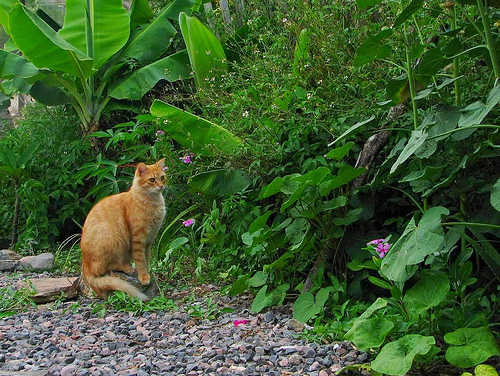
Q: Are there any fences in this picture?
A: No, there are no fences.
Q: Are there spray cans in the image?
A: No, there are no spray cans.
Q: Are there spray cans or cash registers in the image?
A: No, there are no spray cans or cash registers.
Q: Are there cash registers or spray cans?
A: No, there are no spray cans or cash registers.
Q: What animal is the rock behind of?
A: The rock is behind the cat.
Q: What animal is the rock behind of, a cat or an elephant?
A: The rock is behind a cat.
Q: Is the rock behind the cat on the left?
A: Yes, the rock is behind the cat.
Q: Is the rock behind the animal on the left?
A: Yes, the rock is behind the cat.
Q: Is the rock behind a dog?
A: No, the rock is behind the cat.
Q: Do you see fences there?
A: No, there are no fences.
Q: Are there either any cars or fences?
A: No, there are no fences or cars.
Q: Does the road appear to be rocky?
A: Yes, the road is rocky.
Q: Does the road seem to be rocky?
A: Yes, the road is rocky.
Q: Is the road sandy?
A: No, the road is rocky.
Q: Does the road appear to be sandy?
A: No, the road is rocky.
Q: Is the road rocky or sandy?
A: The road is rocky.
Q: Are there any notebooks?
A: No, there are no notebooks.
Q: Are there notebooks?
A: No, there are no notebooks.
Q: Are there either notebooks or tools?
A: No, there are no notebooks or tools.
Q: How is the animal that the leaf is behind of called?
A: The animal is a cat.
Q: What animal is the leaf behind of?
A: The leaf is behind the cat.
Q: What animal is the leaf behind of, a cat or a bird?
A: The leaf is behind a cat.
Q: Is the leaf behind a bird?
A: No, the leaf is behind the cat.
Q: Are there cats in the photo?
A: Yes, there is a cat.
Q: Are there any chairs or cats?
A: Yes, there is a cat.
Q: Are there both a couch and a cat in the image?
A: No, there is a cat but no couches.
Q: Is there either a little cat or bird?
A: Yes, there is a little cat.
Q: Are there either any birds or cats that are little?
A: Yes, the cat is little.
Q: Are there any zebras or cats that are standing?
A: Yes, the cat is standing.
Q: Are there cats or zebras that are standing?
A: Yes, the cat is standing.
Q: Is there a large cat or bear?
A: Yes, there is a large cat.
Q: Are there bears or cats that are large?
A: Yes, the cat is large.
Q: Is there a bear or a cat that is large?
A: Yes, the cat is large.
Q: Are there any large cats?
A: Yes, there is a large cat.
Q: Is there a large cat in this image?
A: Yes, there is a large cat.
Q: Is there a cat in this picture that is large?
A: Yes, there is a cat that is large.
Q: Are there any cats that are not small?
A: Yes, there is a large cat.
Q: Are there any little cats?
A: Yes, there is a little cat.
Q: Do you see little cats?
A: Yes, there is a little cat.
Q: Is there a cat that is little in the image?
A: Yes, there is a little cat.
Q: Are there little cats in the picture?
A: Yes, there is a little cat.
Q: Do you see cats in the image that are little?
A: Yes, there is a cat that is little.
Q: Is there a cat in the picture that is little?
A: Yes, there is a cat that is little.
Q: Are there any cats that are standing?
A: Yes, there is a cat that is standing.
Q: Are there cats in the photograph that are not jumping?
A: Yes, there is a cat that is standing.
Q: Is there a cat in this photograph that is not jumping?
A: Yes, there is a cat that is standing.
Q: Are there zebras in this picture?
A: No, there are no zebras.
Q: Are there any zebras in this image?
A: No, there are no zebras.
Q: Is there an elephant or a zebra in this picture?
A: No, there are no zebras or elephants.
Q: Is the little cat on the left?
A: Yes, the cat is on the left of the image.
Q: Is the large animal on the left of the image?
A: Yes, the cat is on the left of the image.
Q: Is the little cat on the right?
A: No, the cat is on the left of the image.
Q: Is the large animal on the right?
A: No, the cat is on the left of the image.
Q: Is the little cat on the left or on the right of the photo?
A: The cat is on the left of the image.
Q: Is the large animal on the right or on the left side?
A: The cat is on the left of the image.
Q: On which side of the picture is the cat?
A: The cat is on the left of the image.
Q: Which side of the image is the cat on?
A: The cat is on the left of the image.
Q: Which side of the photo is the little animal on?
A: The cat is on the left of the image.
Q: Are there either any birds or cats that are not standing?
A: No, there is a cat but it is standing.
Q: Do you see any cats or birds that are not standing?
A: No, there is a cat but it is standing.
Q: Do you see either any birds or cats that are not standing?
A: No, there is a cat but it is standing.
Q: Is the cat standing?
A: Yes, the cat is standing.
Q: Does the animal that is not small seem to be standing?
A: Yes, the cat is standing.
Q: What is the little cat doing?
A: The cat is standing.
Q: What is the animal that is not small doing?
A: The cat is standing.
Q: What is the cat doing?
A: The cat is standing.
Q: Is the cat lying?
A: No, the cat is standing.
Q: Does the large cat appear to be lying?
A: No, the cat is standing.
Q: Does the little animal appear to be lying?
A: No, the cat is standing.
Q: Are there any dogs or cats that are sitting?
A: No, there is a cat but it is standing.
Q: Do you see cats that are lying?
A: No, there is a cat but it is standing.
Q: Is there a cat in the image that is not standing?
A: No, there is a cat but it is standing.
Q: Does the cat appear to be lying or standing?
A: The cat is standing.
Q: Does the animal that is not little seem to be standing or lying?
A: The cat is standing.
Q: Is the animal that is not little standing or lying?
A: The cat is standing.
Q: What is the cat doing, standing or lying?
A: The cat is standing.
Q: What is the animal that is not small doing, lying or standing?
A: The cat is standing.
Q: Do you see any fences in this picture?
A: No, there are no fences.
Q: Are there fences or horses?
A: No, there are no fences or horses.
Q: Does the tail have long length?
A: Yes, the tail is long.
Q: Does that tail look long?
A: Yes, the tail is long.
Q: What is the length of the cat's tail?
A: The tail is long.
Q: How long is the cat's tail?
A: The tail is long.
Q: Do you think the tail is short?
A: No, the tail is long.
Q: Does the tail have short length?
A: No, the tail is long.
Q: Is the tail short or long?
A: The tail is long.